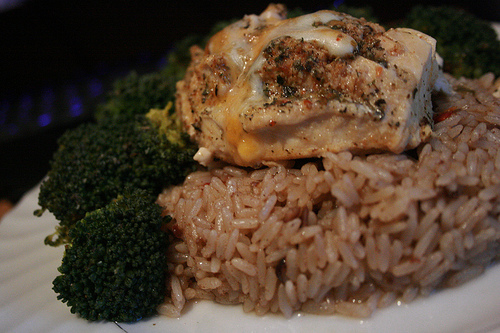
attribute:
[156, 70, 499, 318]
rice — brown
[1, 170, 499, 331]
plate — white, round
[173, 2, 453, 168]
chicken — cooked, seasoned, white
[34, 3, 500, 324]
broccoli — dark green, vegetable, green, uncooked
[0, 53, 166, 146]
fire — blue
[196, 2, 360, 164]
cheese — melted